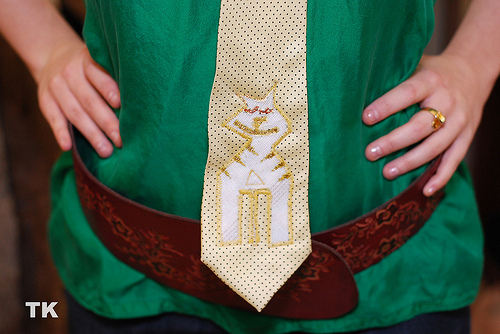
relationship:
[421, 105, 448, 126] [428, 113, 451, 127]
ring with jewel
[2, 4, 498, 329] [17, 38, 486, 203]
hands on hips of person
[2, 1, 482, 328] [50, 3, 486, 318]
person wearing shirt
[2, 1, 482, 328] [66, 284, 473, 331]
person wearing jeans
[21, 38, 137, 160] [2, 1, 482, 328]
hands of a person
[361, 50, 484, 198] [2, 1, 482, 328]
hand of a person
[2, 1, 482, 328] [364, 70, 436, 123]
person has a finger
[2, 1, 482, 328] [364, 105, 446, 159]
person has a finger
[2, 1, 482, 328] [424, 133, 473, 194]
person has a finger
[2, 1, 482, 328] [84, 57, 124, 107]
person has a finger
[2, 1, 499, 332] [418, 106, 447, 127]
person wearing a ring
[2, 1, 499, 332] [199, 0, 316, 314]
person wearing a cat tie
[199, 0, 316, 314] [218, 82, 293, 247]
cat tie has a cat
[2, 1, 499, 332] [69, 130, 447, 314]
person wearing a belt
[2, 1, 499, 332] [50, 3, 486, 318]
person wearing a shirt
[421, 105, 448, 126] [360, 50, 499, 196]
ring on hand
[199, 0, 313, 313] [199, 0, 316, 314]
polka dots on cat tie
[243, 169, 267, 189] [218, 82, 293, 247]
triangle in cat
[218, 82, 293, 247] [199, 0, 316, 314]
cat on cat tie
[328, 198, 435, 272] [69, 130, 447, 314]
design on belt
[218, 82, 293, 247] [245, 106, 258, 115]
cat has eye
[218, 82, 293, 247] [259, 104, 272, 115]
cat has eye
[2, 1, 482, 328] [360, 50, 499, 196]
person has hand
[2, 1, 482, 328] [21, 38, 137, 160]
person has hands